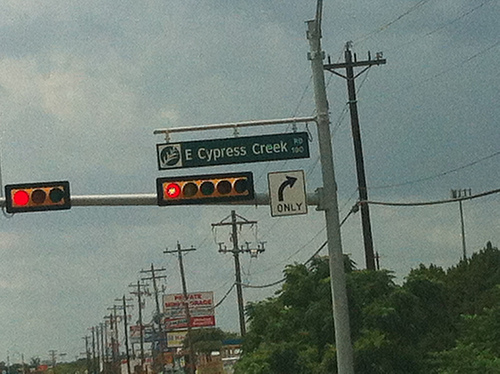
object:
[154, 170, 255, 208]
street light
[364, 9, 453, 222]
telephone lines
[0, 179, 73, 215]
traffic signal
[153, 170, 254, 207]
traffic signal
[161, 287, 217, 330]
billboard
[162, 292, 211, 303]
lettering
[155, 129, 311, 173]
street sign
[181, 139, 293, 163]
lettering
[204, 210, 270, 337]
power poles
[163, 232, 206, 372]
power poles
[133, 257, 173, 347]
power poles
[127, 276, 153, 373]
power poles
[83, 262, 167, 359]
power poles